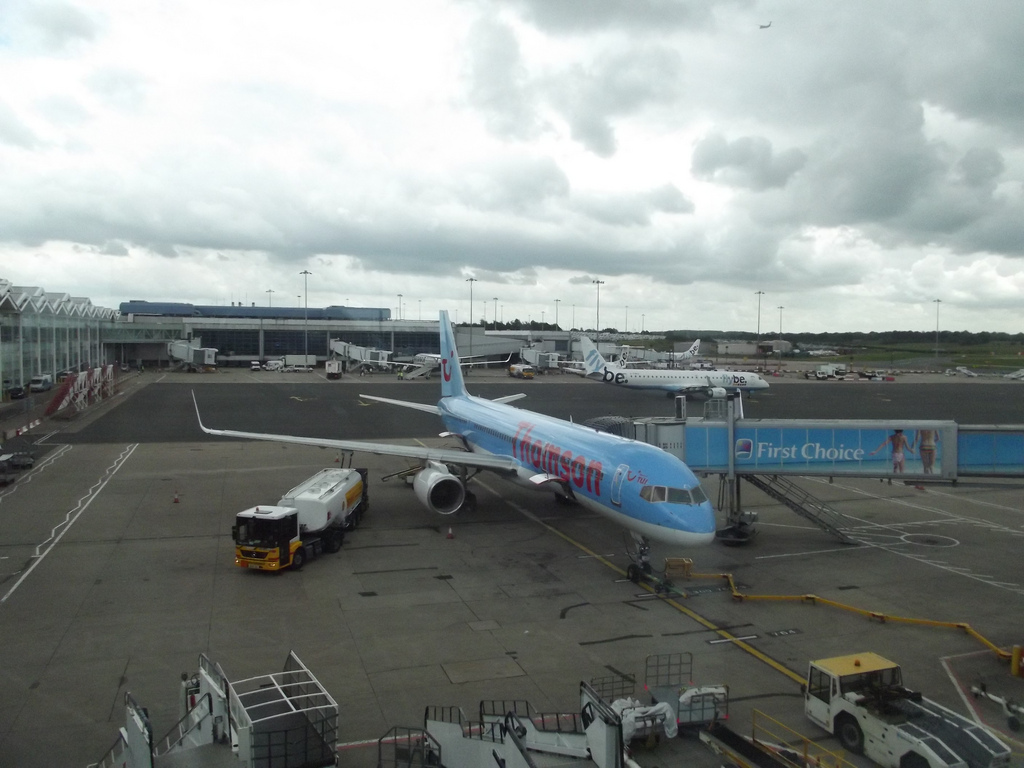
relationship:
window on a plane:
[648, 489, 671, 506] [558, 335, 774, 400]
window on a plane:
[651, 484, 668, 502] [569, 342, 773, 396]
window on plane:
[664, 492, 699, 508] [184, 312, 735, 560]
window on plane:
[666, 487, 691, 504] [558, 335, 774, 400]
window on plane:
[666, 487, 691, 504] [193, 316, 759, 585]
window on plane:
[688, 486, 707, 504] [193, 316, 759, 585]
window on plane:
[666, 487, 691, 504] [547, 328, 778, 409]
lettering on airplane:
[500, 402, 607, 502] [191, 310, 717, 547]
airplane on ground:
[170, 305, 726, 563] [20, 353, 1017, 757]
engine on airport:
[403, 452, 470, 522] [580, 336, 769, 399]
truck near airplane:
[226, 458, 371, 571] [191, 310, 717, 547]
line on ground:
[625, 561, 818, 695] [0, 373, 1024, 768]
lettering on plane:
[512, 421, 600, 495] [184, 312, 735, 560]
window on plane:
[639, 484, 652, 507] [193, 316, 759, 585]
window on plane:
[690, 487, 714, 508] [150, 313, 733, 582]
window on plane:
[633, 484, 671, 507] [560, 337, 773, 411]